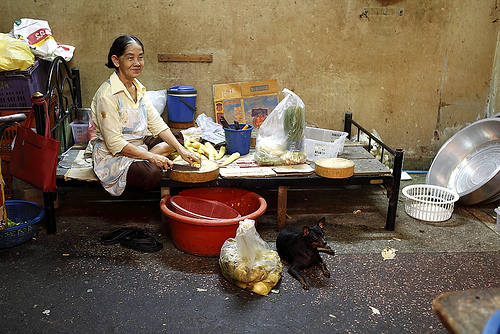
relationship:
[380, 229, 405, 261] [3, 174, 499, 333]
debris on ground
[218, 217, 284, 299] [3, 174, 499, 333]
bag on ground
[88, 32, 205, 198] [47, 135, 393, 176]
lady sitting at table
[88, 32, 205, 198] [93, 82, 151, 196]
lady wearing apron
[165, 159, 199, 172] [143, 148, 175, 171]
knife in lady's hand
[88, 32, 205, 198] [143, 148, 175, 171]
woman has a hand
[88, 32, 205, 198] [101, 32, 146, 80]
woman has a head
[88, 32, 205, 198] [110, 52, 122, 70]
woman has a ear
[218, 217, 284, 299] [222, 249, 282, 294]
bag has yellowy substance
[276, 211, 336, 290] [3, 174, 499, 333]
dog on ground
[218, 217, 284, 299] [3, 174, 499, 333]
sack of banana peel on ground